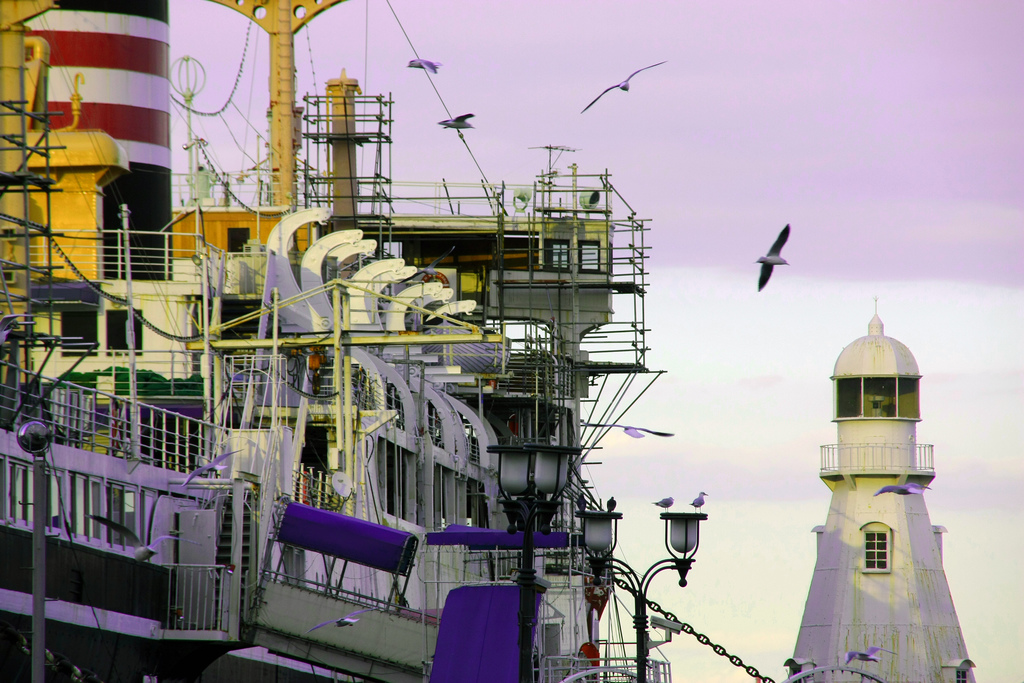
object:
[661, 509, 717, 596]
light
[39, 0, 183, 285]
smokestack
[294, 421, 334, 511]
window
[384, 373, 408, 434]
window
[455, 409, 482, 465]
window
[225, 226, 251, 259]
window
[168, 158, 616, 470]
building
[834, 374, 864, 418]
window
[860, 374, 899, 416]
window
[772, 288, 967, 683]
building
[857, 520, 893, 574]
window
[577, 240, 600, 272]
windows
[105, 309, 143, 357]
window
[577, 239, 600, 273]
boat window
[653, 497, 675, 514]
seagull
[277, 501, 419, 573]
cover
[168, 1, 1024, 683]
air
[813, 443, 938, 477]
railing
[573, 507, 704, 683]
pole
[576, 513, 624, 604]
light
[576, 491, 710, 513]
birds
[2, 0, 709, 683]
boat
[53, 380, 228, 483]
railing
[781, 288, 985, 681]
lighthouse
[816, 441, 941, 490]
walkway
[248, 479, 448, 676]
walkway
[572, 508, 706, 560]
lights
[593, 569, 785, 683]
chain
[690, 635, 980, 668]
dock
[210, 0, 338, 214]
tower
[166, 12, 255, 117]
chain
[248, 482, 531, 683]
entrance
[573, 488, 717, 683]
lamp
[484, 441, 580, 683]
lamp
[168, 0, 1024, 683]
sky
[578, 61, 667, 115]
bird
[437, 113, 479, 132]
bird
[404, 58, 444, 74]
bird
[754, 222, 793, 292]
bird